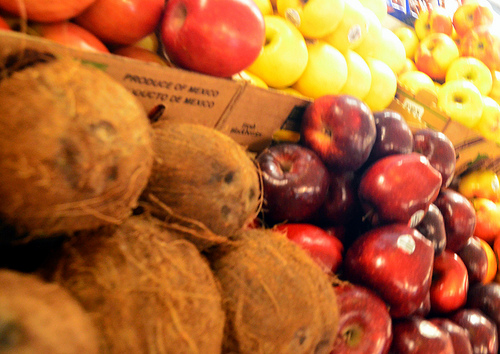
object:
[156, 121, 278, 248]
coconut shell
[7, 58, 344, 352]
coconuts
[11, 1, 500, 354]
fruit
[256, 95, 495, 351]
apple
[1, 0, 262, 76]
apples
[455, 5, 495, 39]
apple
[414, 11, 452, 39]
apple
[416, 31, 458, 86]
apple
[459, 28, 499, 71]
apple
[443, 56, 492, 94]
apple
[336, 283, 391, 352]
apple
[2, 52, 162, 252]
coconut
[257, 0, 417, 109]
apples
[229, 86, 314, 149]
box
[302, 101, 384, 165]
an apple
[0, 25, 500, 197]
box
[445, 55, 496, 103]
apples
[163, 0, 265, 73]
apple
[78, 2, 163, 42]
apple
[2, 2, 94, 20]
apple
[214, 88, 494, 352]
fruit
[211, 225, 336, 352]
shells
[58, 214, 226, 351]
shells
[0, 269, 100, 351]
shells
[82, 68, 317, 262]
coconut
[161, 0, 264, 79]
aplle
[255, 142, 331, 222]
aplle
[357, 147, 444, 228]
aplle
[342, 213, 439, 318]
aplle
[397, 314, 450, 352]
aplle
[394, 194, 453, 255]
apple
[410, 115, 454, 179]
apple